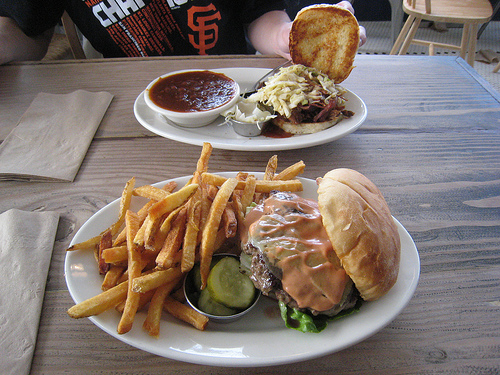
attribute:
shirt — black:
[21, 0, 283, 58]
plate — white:
[63, 171, 421, 366]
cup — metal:
[181, 252, 263, 323]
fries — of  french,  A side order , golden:
[66, 176, 185, 341]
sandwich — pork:
[257, 4, 360, 136]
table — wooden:
[367, 42, 496, 374]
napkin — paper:
[0, 202, 63, 374]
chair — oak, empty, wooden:
[390, 3, 496, 54]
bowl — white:
[142, 67, 241, 129]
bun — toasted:
[288, 4, 359, 84]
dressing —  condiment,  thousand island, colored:
[282, 255, 342, 312]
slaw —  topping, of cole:
[252, 63, 339, 116]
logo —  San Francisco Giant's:
[189, 3, 220, 54]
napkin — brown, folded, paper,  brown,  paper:
[2, 89, 114, 183]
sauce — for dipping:
[160, 75, 227, 105]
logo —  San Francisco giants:
[187, 3, 221, 53]